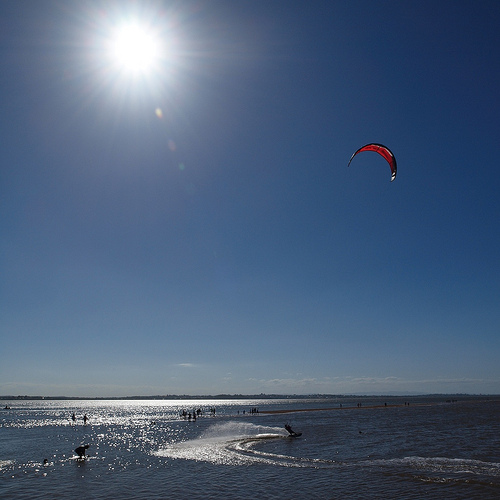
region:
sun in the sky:
[62, 19, 212, 116]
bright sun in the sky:
[59, 7, 210, 100]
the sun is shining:
[46, 5, 233, 114]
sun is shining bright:
[54, 9, 238, 119]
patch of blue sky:
[124, 227, 385, 335]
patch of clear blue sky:
[112, 239, 370, 349]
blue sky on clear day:
[86, 236, 421, 361]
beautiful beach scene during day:
[25, 280, 448, 477]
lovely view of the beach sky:
[50, 207, 434, 464]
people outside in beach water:
[16, 368, 421, 473]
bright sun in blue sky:
[62, 0, 201, 112]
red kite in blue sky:
[360, 128, 407, 186]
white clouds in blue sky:
[21, 145, 92, 219]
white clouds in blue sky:
[42, 266, 107, 310]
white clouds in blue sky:
[178, 255, 236, 309]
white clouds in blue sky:
[231, 311, 291, 365]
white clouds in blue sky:
[332, 253, 383, 308]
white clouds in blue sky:
[355, 308, 409, 336]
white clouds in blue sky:
[245, 172, 300, 259]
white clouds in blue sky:
[261, 35, 326, 77]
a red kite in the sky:
[326, 110, 405, 240]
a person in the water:
[71, 430, 100, 470]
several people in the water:
[44, 387, 260, 442]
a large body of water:
[21, 367, 447, 487]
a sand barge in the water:
[214, 387, 447, 426]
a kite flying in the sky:
[303, 100, 429, 260]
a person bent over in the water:
[66, 437, 100, 474]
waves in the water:
[177, 413, 270, 487]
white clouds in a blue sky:
[210, 353, 460, 393]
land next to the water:
[33, 384, 457, 410]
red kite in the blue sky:
[343, 141, 401, 184]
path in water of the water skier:
[220, 426, 497, 484]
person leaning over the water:
[73, 440, 94, 459]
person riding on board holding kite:
[280, 415, 305, 440]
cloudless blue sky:
[0, 0, 495, 393]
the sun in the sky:
[105, 15, 161, 73]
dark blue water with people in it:
[0, 397, 497, 497]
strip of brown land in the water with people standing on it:
[252, 395, 469, 415]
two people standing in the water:
[67, 410, 92, 422]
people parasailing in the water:
[281, 140, 402, 442]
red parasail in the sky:
[343, 132, 408, 192]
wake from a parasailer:
[218, 420, 480, 493]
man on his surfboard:
[276, 415, 309, 451]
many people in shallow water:
[29, 392, 491, 477]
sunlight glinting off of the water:
[19, 398, 282, 487]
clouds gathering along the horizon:
[9, 357, 482, 400]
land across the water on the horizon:
[4, 384, 487, 414]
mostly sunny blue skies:
[9, 10, 476, 400]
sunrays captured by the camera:
[33, 10, 267, 155]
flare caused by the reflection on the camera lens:
[125, 92, 214, 233]